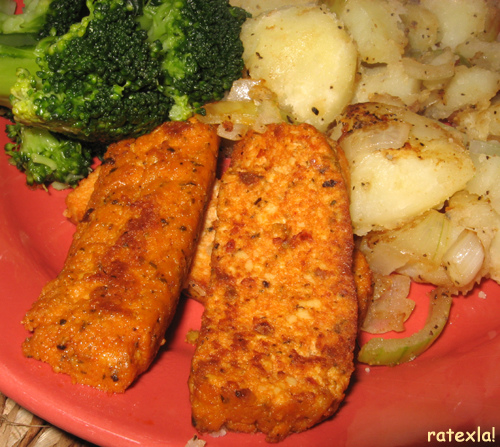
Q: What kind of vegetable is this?
A: Broccoli.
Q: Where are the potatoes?
A: On the right side of the plate.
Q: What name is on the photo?
A: Ratexla.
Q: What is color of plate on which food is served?
A: Pink.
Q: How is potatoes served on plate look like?
A: Fried with pepper and onions.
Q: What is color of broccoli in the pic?
A: Green.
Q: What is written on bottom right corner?
A: Ratexla.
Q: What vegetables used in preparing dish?
A: Broccoli,onion and potatoes.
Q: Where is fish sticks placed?
A: On red plate.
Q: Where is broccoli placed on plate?
A: Towards left of fish sticks.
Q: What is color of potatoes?
A: Bridge and white.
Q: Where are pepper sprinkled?
A: Over potatoes..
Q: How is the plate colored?
A: Red.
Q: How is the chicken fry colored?
A: Brown.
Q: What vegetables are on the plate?
A: Broccoli and potatoes.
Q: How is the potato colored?
A: White.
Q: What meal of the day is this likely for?
A: Dinner.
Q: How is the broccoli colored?
A: Green.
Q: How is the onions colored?
A: Light green.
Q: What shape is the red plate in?
A: Circle.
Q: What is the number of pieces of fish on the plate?
A: Two.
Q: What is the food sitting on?
A: The plate.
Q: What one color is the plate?
A: Orange.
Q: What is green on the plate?
A: Broccoli.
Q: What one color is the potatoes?
A: White.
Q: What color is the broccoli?
A: Green.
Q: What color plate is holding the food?
A: Pink.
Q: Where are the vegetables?
A: On the plate.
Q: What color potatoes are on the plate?
A: White.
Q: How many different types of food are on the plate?
A: Three.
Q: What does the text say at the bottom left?
A: Ratexla.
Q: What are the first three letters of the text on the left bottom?
A: Rat.